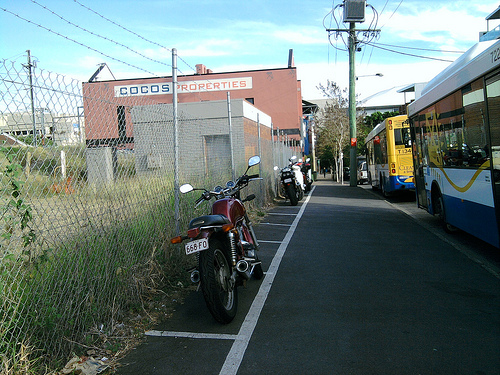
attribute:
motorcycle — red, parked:
[171, 154, 265, 325]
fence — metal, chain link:
[1, 54, 304, 374]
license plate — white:
[179, 235, 211, 255]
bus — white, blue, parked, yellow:
[402, 20, 499, 247]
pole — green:
[344, 20, 362, 187]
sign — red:
[348, 135, 359, 148]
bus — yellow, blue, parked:
[361, 112, 415, 195]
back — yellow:
[382, 111, 414, 184]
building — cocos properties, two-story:
[76, 46, 309, 190]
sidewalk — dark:
[98, 172, 500, 373]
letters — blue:
[119, 83, 173, 97]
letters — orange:
[176, 79, 248, 92]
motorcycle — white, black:
[276, 161, 304, 204]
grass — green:
[1, 142, 266, 373]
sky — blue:
[0, 1, 498, 112]